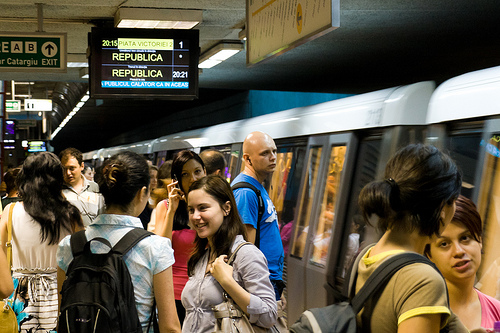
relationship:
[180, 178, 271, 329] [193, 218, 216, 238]
woman has smile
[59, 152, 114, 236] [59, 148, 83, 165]
man has hair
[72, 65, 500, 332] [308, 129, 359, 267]
train has window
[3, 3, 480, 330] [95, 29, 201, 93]
station has sign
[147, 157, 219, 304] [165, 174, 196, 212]
woman has phone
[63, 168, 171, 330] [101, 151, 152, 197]
woman has ponytail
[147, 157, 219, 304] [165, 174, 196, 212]
woman on phone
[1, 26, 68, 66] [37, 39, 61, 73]
sign shows exit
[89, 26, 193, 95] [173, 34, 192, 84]
monitor shows times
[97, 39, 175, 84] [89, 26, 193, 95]
route on monitor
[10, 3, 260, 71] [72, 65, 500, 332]
ceiling above train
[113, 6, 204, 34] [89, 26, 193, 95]
light near monitor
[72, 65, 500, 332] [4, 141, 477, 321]
train near people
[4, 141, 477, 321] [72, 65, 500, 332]
people near train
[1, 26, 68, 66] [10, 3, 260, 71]
sign on ceiling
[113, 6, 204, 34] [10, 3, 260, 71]
light on ceiling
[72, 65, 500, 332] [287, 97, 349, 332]
train has door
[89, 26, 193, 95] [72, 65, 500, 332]
monitor over train